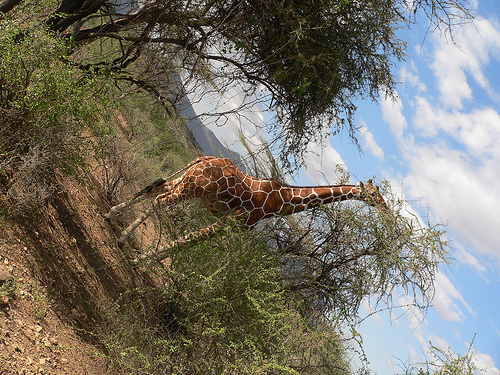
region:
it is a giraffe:
[102, 96, 409, 280]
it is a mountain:
[184, 106, 237, 168]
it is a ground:
[9, 262, 61, 372]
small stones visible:
[12, 246, 54, 374]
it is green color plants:
[192, 273, 328, 348]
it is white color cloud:
[449, 171, 488, 241]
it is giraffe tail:
[127, 166, 190, 199]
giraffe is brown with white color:
[204, 161, 254, 209]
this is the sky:
[407, 26, 425, 42]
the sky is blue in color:
[482, 292, 497, 312]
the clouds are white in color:
[431, 147, 472, 183]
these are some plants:
[207, 234, 439, 374]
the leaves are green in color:
[231, 289, 281, 324]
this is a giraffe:
[120, 117, 410, 262]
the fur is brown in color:
[217, 177, 249, 204]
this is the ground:
[9, 248, 110, 353]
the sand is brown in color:
[33, 288, 57, 319]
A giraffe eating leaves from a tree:
[93, 142, 403, 289]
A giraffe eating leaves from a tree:
[100, 148, 403, 278]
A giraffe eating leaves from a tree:
[96, 145, 399, 290]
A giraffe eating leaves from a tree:
[97, 142, 400, 275]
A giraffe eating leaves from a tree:
[91, 145, 404, 285]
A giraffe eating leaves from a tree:
[95, 148, 396, 281]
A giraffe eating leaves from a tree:
[93, 145, 408, 275]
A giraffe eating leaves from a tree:
[95, 151, 403, 281]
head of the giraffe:
[346, 159, 420, 218]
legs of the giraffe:
[105, 164, 202, 287]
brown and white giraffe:
[204, 163, 280, 218]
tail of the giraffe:
[116, 133, 223, 208]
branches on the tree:
[299, 229, 380, 274]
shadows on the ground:
[0, 236, 125, 326]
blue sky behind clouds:
[383, 83, 468, 125]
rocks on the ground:
[0, 269, 110, 371]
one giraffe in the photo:
[66, 157, 423, 327]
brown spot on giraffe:
[350, 185, 360, 196]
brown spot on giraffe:
[338, 186, 353, 194]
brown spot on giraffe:
[338, 193, 346, 200]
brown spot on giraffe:
[331, 184, 343, 198]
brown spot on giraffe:
[312, 186, 333, 201]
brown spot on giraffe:
[298, 186, 313, 200]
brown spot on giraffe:
[291, 187, 301, 197]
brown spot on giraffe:
[280, 185, 293, 203]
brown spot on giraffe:
[263, 187, 282, 217]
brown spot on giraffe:
[248, 190, 265, 207]